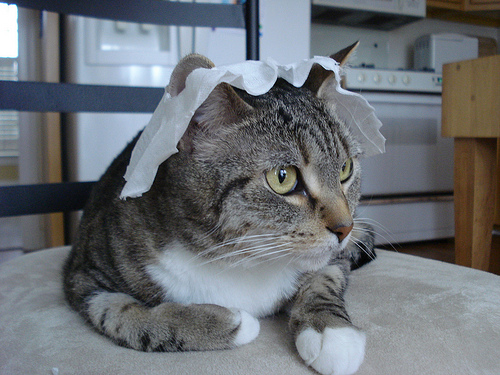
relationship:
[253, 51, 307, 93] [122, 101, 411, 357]
tissue on cat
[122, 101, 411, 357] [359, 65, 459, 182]
cat near oven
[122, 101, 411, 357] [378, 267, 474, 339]
cat on seat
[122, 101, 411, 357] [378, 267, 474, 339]
cat on top of seat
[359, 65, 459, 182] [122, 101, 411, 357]
oven behind cat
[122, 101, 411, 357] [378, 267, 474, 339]
cat in seat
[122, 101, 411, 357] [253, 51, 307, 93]
cat with tissue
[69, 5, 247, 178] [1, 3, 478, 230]
refrigerator in kitchen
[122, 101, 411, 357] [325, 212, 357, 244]
cat has nose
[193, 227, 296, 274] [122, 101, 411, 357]
whiskers are on cat